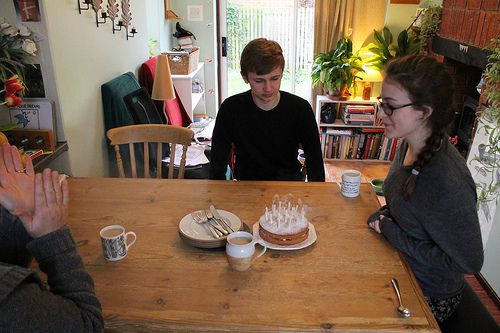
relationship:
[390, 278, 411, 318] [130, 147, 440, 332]
spoon ont table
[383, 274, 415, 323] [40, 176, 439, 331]
spoon on table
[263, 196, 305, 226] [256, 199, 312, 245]
candles on top of cake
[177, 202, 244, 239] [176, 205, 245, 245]
silverware on plates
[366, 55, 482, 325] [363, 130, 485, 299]
girl wearing shirt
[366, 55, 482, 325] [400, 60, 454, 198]
girl has braid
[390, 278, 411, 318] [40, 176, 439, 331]
spoon on table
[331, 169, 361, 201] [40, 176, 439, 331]
mug on table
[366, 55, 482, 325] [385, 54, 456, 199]
girl has hair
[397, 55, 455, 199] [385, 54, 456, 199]
french braid in hair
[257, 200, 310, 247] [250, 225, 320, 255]
cake on plate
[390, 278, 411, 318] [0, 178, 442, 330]
spoon laying on table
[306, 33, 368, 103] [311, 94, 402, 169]
plant on shelf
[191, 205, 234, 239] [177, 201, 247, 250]
silverware on top of plates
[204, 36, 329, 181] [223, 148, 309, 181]
man sitting in chair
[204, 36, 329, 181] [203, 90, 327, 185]
man wearing top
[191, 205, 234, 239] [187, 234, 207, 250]
silverware on plates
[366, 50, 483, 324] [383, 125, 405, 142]
girl has chin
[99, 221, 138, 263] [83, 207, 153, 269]
cup of coffee.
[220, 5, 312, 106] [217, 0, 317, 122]
sun shining door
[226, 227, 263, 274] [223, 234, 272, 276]
pitcher of cream